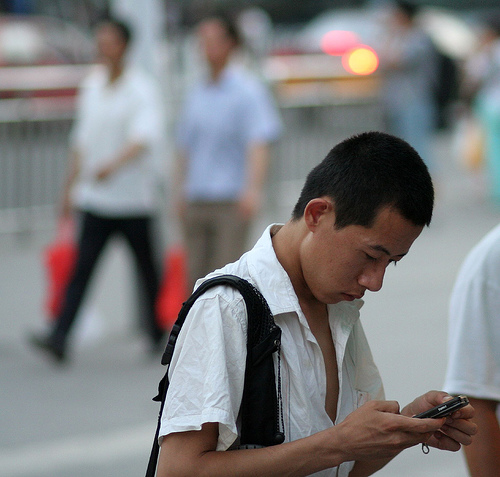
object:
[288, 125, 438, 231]
black hair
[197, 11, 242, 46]
black hair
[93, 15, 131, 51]
black hair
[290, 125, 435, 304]
head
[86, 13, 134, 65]
head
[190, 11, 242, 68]
head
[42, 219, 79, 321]
red bag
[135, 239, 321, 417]
shoulder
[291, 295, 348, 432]
chest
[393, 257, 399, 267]
lashes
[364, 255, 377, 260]
lashes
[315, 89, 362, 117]
rod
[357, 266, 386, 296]
nose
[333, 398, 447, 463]
hand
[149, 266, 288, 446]
strap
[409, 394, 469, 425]
cellphone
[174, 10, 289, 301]
person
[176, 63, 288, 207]
shirt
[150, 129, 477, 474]
person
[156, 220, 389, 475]
shirt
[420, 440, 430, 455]
strap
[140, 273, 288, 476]
bag